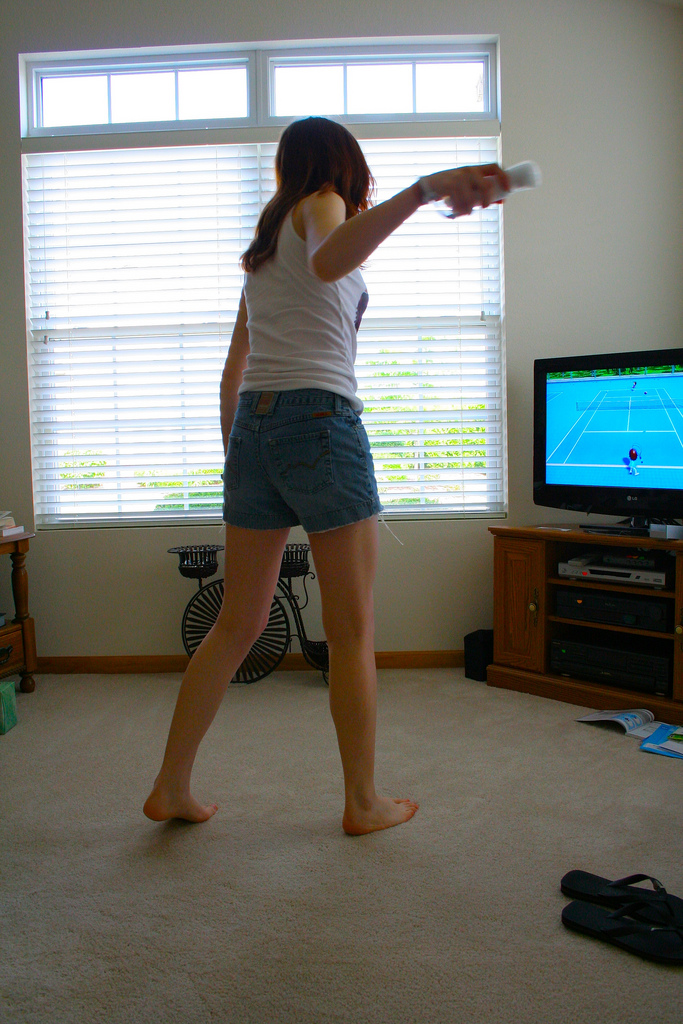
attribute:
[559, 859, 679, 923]
flip flop — black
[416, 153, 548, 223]
remote — white, wii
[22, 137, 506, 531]
blinds — white, plastic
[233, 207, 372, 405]
shirt — white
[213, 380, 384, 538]
shorts — cut off, jean, blue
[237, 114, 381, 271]
hair — long, brown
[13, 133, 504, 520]
window blinds — white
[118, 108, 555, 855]
girl — barefoot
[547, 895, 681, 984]
flip flop — black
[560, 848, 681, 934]
flip flop — black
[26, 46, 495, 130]
window — long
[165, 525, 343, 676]
furniture — iron, black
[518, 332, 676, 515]
tv screen — black, flat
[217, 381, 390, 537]
jean shorts — blue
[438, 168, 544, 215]
game controller — white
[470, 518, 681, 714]
tv stand — brown